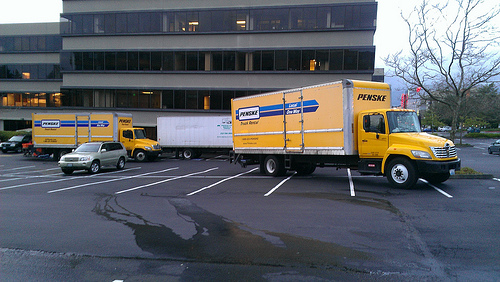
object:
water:
[83, 187, 381, 278]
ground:
[0, 148, 498, 279]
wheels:
[385, 156, 414, 189]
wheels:
[89, 161, 101, 174]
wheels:
[182, 148, 197, 159]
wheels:
[134, 149, 152, 163]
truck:
[31, 111, 163, 161]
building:
[2, 0, 387, 137]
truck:
[155, 116, 239, 160]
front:
[358, 109, 462, 188]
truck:
[227, 78, 460, 189]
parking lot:
[5, 133, 498, 279]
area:
[1, 106, 464, 252]